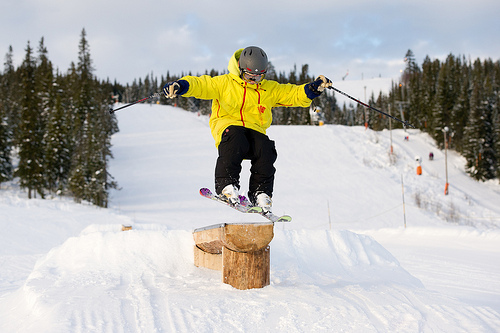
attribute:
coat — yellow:
[176, 49, 323, 146]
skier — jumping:
[162, 46, 334, 225]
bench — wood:
[192, 218, 276, 290]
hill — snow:
[25, 220, 431, 332]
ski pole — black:
[324, 82, 416, 132]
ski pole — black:
[105, 87, 180, 118]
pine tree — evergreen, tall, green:
[1, 26, 123, 210]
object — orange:
[414, 155, 423, 175]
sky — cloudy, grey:
[1, 1, 499, 82]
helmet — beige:
[236, 46, 268, 74]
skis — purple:
[196, 185, 291, 223]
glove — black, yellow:
[314, 75, 333, 91]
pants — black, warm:
[212, 124, 277, 207]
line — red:
[240, 81, 248, 127]